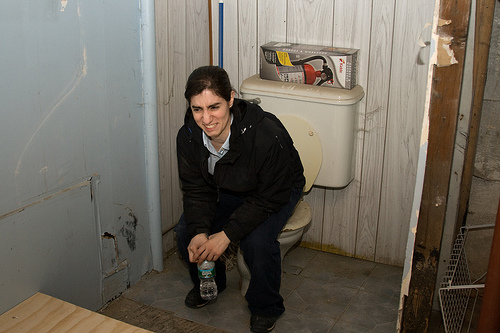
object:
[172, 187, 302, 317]
jeans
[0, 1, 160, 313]
wall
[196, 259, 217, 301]
bottle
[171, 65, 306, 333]
woman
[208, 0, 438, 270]
panels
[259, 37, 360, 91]
box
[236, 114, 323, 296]
toilet bowl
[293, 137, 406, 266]
brick building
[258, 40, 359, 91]
extinguisher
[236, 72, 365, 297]
toilet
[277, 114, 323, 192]
lid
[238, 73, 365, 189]
toilet tank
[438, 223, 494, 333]
tray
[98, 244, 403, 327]
floor